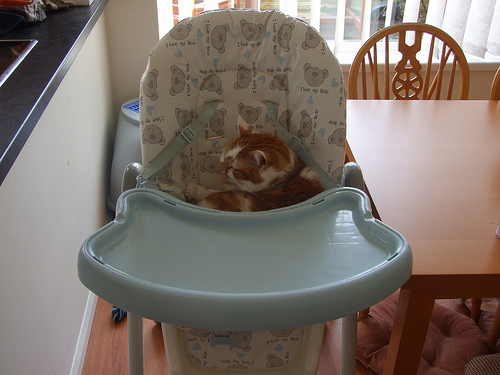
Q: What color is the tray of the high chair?
A: Light blue.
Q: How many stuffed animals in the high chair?
A: One.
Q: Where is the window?
A: Behind the chairs.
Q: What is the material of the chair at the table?
A: Wood.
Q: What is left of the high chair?
A: Counter.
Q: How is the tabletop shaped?
A: Rectangular.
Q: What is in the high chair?
A: Stuffed animal.